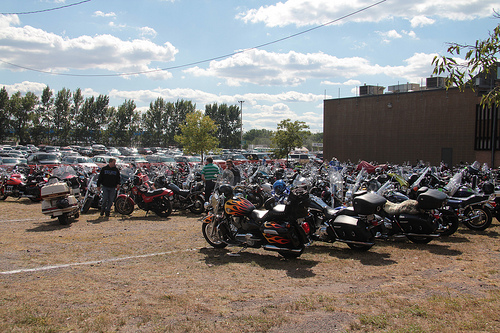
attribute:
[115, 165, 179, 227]
motorcycle — red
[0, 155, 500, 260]
motorcycles — parked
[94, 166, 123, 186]
sweatshirt — black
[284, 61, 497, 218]
building — brown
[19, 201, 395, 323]
field — bare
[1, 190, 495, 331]
field — dry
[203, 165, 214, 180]
shirt — green